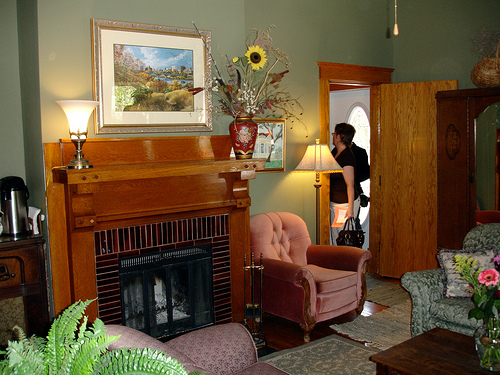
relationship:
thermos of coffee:
[1, 171, 36, 239] [25, 206, 44, 235]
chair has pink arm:
[248, 207, 380, 344] [307, 242, 376, 270]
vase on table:
[470, 314, 500, 374] [361, 323, 475, 375]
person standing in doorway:
[323, 118, 372, 250] [326, 77, 378, 274]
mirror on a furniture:
[470, 99, 500, 224] [430, 85, 499, 228]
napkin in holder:
[33, 204, 40, 234] [25, 206, 44, 235]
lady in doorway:
[323, 118, 372, 250] [326, 77, 378, 274]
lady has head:
[323, 118, 372, 250] [328, 119, 366, 156]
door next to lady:
[364, 73, 439, 278] [323, 118, 372, 250]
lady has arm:
[323, 118, 372, 250] [339, 157, 360, 220]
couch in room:
[248, 207, 380, 344] [2, 3, 498, 370]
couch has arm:
[398, 219, 491, 339] [397, 262, 445, 299]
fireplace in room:
[86, 212, 229, 328] [2, 3, 498, 370]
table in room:
[361, 323, 475, 375] [2, 3, 498, 370]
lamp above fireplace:
[55, 97, 102, 171] [86, 212, 229, 328]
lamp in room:
[54, 96, 102, 170] [2, 3, 498, 370]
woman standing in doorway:
[323, 118, 372, 250] [326, 77, 378, 274]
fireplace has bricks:
[86, 212, 229, 328] [85, 206, 238, 329]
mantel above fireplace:
[36, 128, 273, 217] [86, 212, 229, 328]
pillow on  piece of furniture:
[434, 246, 499, 300] [398, 219, 491, 339]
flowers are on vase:
[434, 246, 499, 300] [470, 314, 500, 374]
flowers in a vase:
[209, 38, 270, 115] [225, 111, 262, 159]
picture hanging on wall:
[86, 16, 217, 139] [38, 0, 250, 136]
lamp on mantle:
[54, 96, 102, 170] [36, 128, 273, 217]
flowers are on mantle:
[209, 38, 270, 115] [36, 128, 273, 217]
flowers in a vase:
[241, 42, 269, 71] [225, 111, 262, 159]